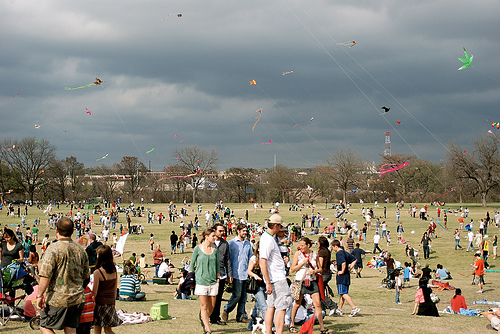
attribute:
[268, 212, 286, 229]
cap — tan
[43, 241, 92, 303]
shirt — camouflage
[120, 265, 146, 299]
woman — sitting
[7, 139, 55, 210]
tree — bare, leafless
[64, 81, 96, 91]
tail — green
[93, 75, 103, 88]
kite — colorful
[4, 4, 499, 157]
sky — cloudy, dark, overcast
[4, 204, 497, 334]
field — flat, grassy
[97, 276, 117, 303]
shirt — brown, sleeveless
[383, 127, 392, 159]
tower — white, red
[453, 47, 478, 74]
kite — green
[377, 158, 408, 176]
kite — pink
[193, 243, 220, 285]
shirt — green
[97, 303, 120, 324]
skirt — plaid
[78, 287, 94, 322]
shirt — striped, orange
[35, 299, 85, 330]
pants — gray, grey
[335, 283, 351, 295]
shorts — blue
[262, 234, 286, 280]
shirt — white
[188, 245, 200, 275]
sleeves — long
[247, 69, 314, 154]
kites — flying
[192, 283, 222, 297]
shorts — white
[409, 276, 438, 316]
woman — sitting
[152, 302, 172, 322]
cooler — small, green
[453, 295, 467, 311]
shirt — orange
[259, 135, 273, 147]
kite — pink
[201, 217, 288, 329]
people — walking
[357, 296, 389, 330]
grass — short